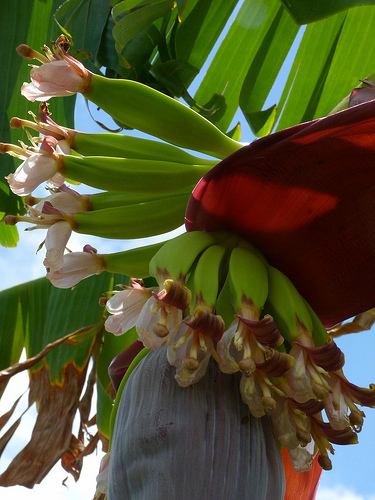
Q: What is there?
A: Plant.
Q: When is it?
A: Daytime.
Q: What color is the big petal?
A: Red.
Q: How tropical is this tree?
A: Very tropical.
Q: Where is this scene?
A: Next to a tree.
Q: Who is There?
A: No one.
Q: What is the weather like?
A: Fair.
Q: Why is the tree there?
A: Natural.